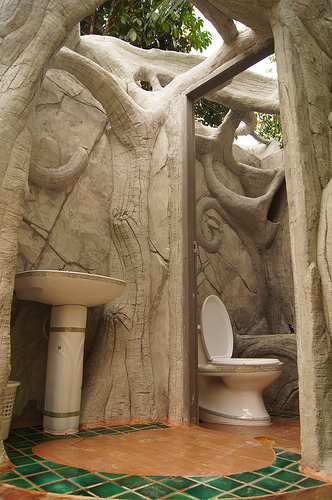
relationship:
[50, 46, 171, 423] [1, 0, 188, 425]
wooden trunk on wall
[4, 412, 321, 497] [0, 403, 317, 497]
tile on floor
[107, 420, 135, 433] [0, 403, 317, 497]
tile in floor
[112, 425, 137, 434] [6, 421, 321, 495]
tile in floor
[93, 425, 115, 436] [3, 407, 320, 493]
tile in floor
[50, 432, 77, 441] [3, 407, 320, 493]
tile in floor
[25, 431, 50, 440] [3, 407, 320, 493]
tile in floor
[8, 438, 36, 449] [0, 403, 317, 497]
tile in floor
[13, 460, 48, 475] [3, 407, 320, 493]
tile in floor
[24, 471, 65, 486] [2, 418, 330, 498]
tile in floor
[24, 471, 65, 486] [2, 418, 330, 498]
tile on floor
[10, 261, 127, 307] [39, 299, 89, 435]
sink on pedestal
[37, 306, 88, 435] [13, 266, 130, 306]
pedestal supporting sink